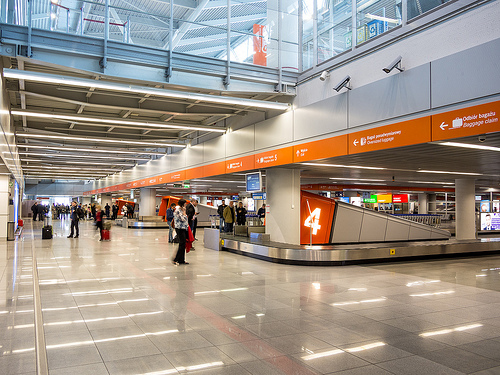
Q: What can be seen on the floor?
A: Reflections of lights.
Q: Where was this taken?
A: Airport.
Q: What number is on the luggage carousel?
A: 4.